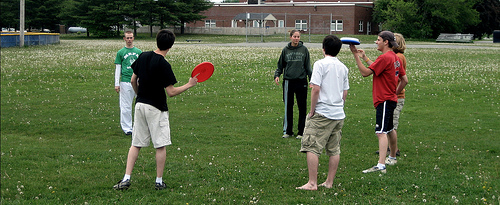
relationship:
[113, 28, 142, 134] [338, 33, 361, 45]
kid playing with frisbee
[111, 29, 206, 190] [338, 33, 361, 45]
boy playing with frisbee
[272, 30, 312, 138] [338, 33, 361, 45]
girl playing with frisbee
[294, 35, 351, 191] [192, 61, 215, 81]
boy playing with frisbee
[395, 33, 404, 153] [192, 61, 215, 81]
kid playing with frisbee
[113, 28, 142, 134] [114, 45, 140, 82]
kid has green shirt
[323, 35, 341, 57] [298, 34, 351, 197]
head of man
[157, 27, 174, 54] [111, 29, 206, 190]
head of boy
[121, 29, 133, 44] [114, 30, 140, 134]
head of man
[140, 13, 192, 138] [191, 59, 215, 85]
boy throwing frisbee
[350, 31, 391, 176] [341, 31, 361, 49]
boy has frisbee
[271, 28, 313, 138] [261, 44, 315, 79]
girl wearing hoodie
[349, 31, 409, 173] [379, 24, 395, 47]
boy wearing cap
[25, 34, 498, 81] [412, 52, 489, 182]
flowers blooming in field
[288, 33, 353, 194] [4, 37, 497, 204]
boy on field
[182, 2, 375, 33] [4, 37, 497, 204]
building behind field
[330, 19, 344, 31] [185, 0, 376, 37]
window on building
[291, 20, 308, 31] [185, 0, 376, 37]
window on building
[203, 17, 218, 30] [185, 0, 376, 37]
window on building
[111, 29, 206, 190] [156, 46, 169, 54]
boy has neck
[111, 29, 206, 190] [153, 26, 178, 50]
boy has hair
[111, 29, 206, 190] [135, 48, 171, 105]
boy has back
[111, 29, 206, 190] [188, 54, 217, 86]
boy has hand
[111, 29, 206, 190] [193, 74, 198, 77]
boy has finger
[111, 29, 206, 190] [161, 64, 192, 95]
boy has arm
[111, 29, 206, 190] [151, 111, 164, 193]
boy has leg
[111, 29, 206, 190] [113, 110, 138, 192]
boy has leg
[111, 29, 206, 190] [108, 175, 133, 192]
boy has foot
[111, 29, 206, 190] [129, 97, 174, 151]
boy wearing shorts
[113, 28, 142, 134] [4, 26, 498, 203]
kid standing in grass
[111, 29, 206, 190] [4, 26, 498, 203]
boy standing in grass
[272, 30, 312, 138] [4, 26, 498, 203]
girl standing in grass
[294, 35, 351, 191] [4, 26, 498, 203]
boy standing in grass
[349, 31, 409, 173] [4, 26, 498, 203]
boy standing in grass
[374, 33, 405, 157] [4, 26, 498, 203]
kid standing in grass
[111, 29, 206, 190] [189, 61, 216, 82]
boy holding frisbee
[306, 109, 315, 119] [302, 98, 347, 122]
hand on hip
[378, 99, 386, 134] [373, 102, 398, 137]
stripe on side of shorts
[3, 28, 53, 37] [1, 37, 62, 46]
stripe at top of fence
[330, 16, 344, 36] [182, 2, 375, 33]
window on side of building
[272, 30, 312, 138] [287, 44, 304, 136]
girl wearing clothes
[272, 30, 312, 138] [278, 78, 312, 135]
girl wearing pants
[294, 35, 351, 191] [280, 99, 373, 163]
boy wearing shorts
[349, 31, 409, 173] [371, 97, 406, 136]
boy wearing black shorts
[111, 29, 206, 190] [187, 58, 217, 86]
boy holding frisbee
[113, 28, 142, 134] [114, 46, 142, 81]
kid wearing green shirt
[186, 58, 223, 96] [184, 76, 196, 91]
frisbee in hand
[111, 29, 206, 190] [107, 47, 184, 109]
boy in shirt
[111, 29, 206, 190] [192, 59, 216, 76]
boy holding frisbee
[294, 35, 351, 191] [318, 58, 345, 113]
boy in shirt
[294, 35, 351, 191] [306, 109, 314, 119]
boy with hand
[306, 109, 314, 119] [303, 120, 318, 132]
hand in pocket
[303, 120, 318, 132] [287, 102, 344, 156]
pocket in shorts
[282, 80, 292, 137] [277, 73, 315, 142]
stripe on sweatpants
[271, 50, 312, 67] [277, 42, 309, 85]
logo on front of hoodie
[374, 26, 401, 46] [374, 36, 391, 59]
cap on head